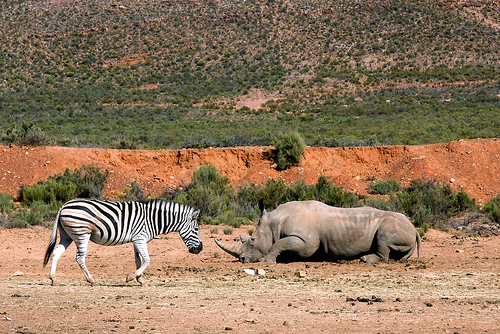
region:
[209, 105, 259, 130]
the grass is green in color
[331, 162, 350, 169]
this is the ground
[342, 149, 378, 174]
the ground is sandy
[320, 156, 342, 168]
the sand is brown in color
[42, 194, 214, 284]
this is a zebra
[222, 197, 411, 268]
this is a rhino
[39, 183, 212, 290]
the zebra is walking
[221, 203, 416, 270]
the rhino is on the ground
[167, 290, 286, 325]
Stone littered dirt ground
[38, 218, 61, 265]
A long swishing tail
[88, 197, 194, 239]
Stripped black and white pattern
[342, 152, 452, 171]
Large mould of soil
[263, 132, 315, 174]
Small thick green shrub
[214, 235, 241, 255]
Thick short rhino tusk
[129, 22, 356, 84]
Large expanse of bushes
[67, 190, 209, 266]
A zebra in motion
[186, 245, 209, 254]
Large dark zebra nose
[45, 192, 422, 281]
a zebra in front of a rhino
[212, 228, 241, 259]
the horn of a rhino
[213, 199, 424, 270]
a rhino laying down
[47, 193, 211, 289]
a zebra walking towards a rhino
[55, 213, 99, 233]
two brown stripes on a zebra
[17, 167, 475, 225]
shrubs in the background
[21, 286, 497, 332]
rocks and pebbles in the foreground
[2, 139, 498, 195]
red dirt on a hill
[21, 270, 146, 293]
the zebra's shadow on the ground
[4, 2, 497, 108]
many shrubs on a hill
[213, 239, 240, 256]
The horn on the rhino's face.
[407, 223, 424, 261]
The tail of the rhino.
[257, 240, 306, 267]
The front leg of the rhino.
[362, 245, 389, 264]
The back leg of the rhino.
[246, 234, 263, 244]
The eye of the rhino.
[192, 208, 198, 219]
The ear of the zebra.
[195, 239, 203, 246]
The nose of the zebra.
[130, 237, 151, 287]
The front legs of the zebra.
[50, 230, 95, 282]
The back legs of the zebra.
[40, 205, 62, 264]
The tail of the zebra.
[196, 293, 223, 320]
part of a ground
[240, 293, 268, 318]
part of a ground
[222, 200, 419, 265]
rhinocerous laying on the dirt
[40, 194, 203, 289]
zebra beside the rhino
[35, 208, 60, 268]
black and white tail of the zebra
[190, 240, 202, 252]
black nose and mouth of the zebra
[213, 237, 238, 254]
horn on the rhinocerous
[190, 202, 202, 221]
ears of the zebra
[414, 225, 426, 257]
tail of the rhinocerous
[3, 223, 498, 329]
dirt the rhinocerous is laying on